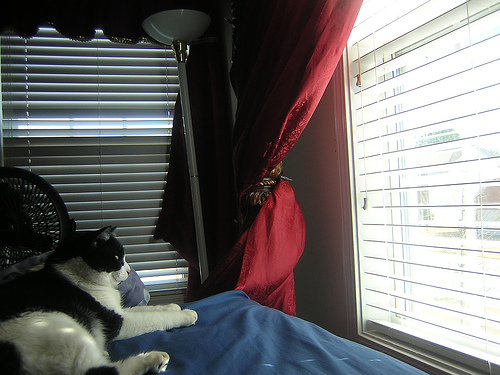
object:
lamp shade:
[140, 8, 216, 49]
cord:
[359, 221, 500, 232]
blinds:
[343, 0, 499, 375]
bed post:
[173, 40, 208, 286]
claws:
[180, 307, 200, 328]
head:
[50, 216, 133, 289]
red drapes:
[150, 0, 364, 319]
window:
[340, 0, 499, 375]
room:
[0, 0, 499, 375]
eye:
[113, 252, 122, 261]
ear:
[95, 224, 119, 244]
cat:
[0, 214, 203, 373]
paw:
[144, 347, 177, 373]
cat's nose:
[120, 260, 131, 275]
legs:
[106, 308, 184, 344]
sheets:
[107, 288, 436, 374]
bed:
[104, 288, 434, 374]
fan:
[0, 165, 73, 272]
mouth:
[114, 275, 128, 286]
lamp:
[140, 5, 216, 287]